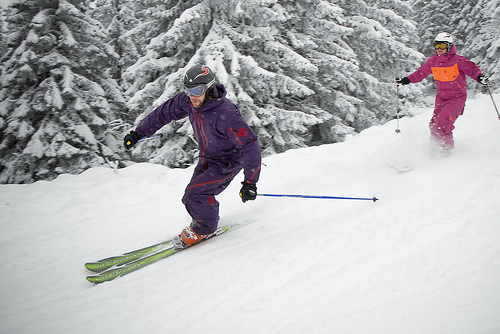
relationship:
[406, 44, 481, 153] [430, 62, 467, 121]
snowsuit has some orange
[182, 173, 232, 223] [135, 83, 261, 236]
stripes on snowsuit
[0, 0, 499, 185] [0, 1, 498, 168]
pine trees covered with snow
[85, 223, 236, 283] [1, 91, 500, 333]
skis on ground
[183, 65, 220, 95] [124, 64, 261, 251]
helmet on man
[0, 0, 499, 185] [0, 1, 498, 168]
pine trees have snow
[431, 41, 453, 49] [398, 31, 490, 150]
goggles on person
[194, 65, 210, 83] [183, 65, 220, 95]
markings on helmet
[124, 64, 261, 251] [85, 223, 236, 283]
man on skis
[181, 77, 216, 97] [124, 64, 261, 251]
goggles on man